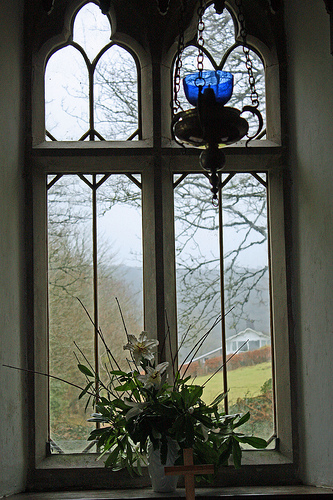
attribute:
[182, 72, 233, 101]
glass — blue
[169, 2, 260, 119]
chains — hanging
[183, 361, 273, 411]
grass — green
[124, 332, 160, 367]
flowers — white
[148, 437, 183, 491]
vase — white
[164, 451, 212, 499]
cross — wood, brown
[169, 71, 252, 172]
candle — hanging, blue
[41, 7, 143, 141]
window — small, closed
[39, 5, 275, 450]
window — long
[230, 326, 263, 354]
house — white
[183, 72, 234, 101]
lamp — blue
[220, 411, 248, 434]
leaf — green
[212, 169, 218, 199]
rod — iron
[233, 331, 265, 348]
building — white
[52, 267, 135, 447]
trees — green, bare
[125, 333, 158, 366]
lily — white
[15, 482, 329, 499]
lidge — cement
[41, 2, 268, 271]
sky — blue, cloudy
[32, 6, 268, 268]
clouds — white